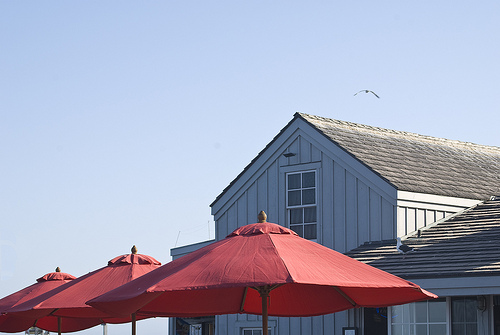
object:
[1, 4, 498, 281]
sky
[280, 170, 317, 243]
window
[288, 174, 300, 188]
pane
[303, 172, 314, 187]
pane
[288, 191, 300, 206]
pane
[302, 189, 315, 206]
pane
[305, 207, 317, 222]
pane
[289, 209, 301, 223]
glass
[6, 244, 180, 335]
red umbrellas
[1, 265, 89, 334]
red umbrellas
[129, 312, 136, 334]
pole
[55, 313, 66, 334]
pole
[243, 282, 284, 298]
assembly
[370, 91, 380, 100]
wing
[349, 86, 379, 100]
bird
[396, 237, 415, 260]
seagull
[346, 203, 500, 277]
roof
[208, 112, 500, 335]
building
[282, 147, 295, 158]
light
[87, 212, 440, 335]
patio umbrella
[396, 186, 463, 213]
fresher board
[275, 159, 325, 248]
frame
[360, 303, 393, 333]
window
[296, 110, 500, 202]
roof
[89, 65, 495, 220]
exterior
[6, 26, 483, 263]
daytime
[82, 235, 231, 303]
panel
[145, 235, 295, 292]
panel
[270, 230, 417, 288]
panel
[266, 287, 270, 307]
pull cord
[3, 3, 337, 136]
air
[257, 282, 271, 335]
pole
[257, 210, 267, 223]
tip